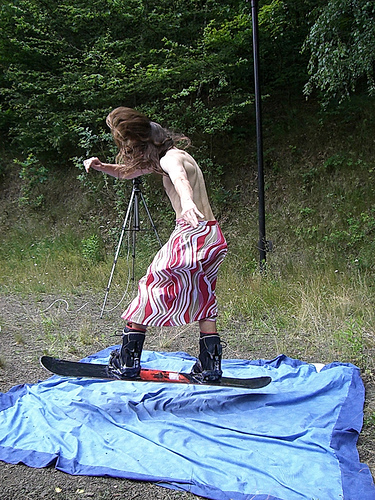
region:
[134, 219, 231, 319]
red and white swirl design skit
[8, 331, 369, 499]
large blue blanket on ground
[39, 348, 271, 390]
black and red waterboard on land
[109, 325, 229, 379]
black snap in boots on waterboard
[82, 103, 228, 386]
white man balancing on waterboard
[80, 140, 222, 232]
muscular and thin stature of man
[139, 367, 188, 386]
red patch on black skateboard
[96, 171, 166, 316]
silver camera tripod in background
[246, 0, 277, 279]
tall black metal pole in background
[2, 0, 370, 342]
green trees and undergrowth behind man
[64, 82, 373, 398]
a man in a dress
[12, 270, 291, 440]
he has black boots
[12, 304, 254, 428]
he is on a scateboard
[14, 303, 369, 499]
the mat is blue in colour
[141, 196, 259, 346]
the dress is red with strippes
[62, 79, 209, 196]
the hair is brown in colour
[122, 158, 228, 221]
he is shirtless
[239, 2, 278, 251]
the pole is black in colour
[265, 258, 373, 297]
the grass is gren in colour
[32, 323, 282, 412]
the scateboard is black in colour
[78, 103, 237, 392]
this is a person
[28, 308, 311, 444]
this is a skate board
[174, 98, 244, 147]
a branch of a tree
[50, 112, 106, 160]
a branch of a tree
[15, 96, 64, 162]
a branch of a tree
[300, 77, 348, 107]
a branch of a tree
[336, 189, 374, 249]
a branch of a tree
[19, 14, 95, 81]
a branch of a tree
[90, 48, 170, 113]
a branch of a tree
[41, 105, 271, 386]
man in a skirt on a snowboard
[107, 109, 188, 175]
hairy mask on a man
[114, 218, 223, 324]
red and gray patterned skirt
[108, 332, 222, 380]
black ski boots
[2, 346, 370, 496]
blue blanket on the ground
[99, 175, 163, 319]
a camera tripod behind the man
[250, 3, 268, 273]
black pole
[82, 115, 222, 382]
man in a skirt and Chewbacca mask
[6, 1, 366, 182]
trees on a hill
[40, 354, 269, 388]
red and black snowboard